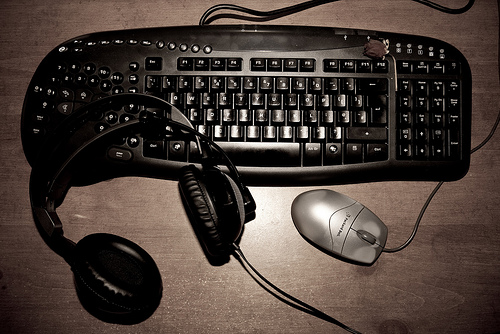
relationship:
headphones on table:
[26, 91, 256, 326] [0, 4, 499, 332]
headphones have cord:
[42, 87, 247, 319] [227, 232, 340, 332]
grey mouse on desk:
[290, 185, 390, 270] [0, 0, 497, 331]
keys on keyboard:
[26, 37, 466, 171] [32, 24, 455, 167]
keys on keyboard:
[50, 37, 454, 164] [11, 12, 495, 205]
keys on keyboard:
[185, 91, 215, 118] [19, 22, 470, 186]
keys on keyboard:
[213, 94, 238, 129] [19, 22, 470, 186]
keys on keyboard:
[228, 88, 260, 136] [19, 22, 470, 186]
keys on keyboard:
[255, 86, 290, 137] [19, 22, 470, 186]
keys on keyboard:
[284, 86, 317, 137] [19, 22, 470, 186]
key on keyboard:
[238, 108, 249, 121] [19, 22, 470, 186]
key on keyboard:
[224, 107, 236, 121] [19, 22, 470, 186]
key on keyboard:
[206, 107, 218, 122] [19, 22, 470, 186]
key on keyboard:
[218, 92, 229, 106] [19, 22, 470, 186]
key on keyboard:
[202, 91, 215, 106] [19, 22, 470, 186]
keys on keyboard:
[334, 95, 356, 110] [19, 22, 470, 186]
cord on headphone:
[228, 243, 355, 333] [22, 87, 257, 327]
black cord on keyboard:
[197, 1, 477, 28] [19, 22, 470, 186]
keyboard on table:
[19, 22, 470, 186] [0, 4, 499, 332]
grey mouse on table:
[290, 187, 389, 267] [0, 4, 499, 332]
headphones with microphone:
[26, 91, 256, 326] [138, 108, 170, 128]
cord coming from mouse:
[386, 123, 498, 258] [283, 179, 405, 267]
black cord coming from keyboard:
[197, 1, 484, 28] [19, 22, 470, 186]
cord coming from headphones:
[228, 243, 355, 333] [26, 91, 256, 326]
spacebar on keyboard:
[206, 134, 300, 167] [19, 22, 470, 186]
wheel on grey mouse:
[360, 233, 376, 243] [290, 187, 389, 267]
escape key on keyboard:
[144, 54, 164, 71] [159, 34, 394, 179]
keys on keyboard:
[289, 76, 352, 121] [19, 22, 470, 186]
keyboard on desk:
[19, 22, 470, 186] [0, 0, 497, 331]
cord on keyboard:
[208, 177, 415, 325] [61, 35, 491, 222]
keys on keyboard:
[164, 92, 222, 130] [29, 27, 464, 204]